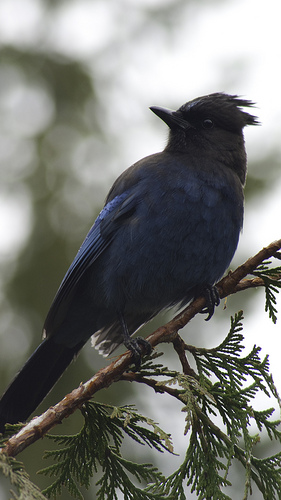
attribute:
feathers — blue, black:
[67, 202, 132, 265]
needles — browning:
[106, 400, 173, 456]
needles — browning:
[151, 365, 232, 456]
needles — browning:
[236, 399, 265, 498]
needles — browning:
[0, 447, 50, 498]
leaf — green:
[229, 317, 243, 326]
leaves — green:
[166, 322, 280, 498]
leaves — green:
[141, 370, 244, 460]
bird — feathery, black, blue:
[64, 70, 264, 274]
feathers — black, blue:
[31, 183, 190, 329]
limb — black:
[31, 245, 275, 434]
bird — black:
[28, 65, 270, 371]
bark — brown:
[90, 371, 123, 386]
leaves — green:
[53, 411, 152, 495]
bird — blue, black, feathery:
[3, 90, 258, 425]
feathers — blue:
[145, 203, 208, 253]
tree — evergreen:
[1, 238, 279, 498]